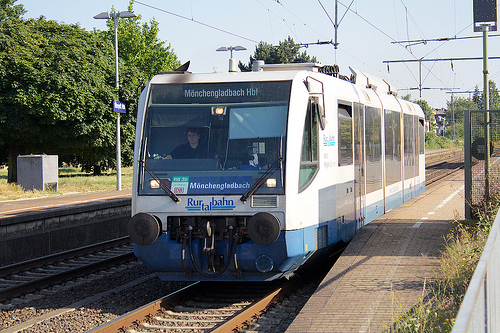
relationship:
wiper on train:
[128, 137, 210, 224] [117, 57, 347, 275]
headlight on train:
[146, 176, 162, 190] [121, 53, 435, 289]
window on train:
[144, 100, 294, 173] [121, 72, 427, 291]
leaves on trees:
[61, 87, 66, 92] [1, 1, 183, 172]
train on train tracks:
[121, 72, 427, 291] [0, 147, 471, 328]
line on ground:
[359, 160, 495, 329] [280, 155, 498, 331]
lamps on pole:
[95, 1, 168, 30] [87, 19, 159, 242]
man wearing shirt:
[150, 110, 219, 197] [158, 110, 210, 157]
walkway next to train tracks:
[287, 153, 487, 331] [0, 147, 471, 328]